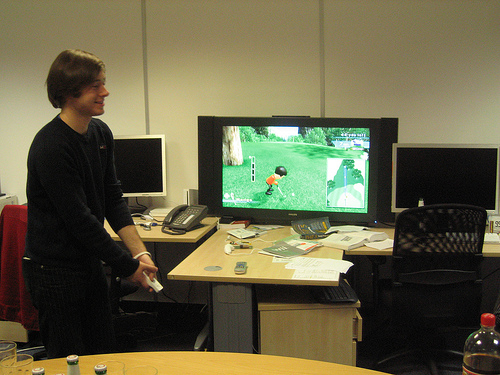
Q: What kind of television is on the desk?
A: An LED.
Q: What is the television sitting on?
A: A desk.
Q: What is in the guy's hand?
A: A wii remote.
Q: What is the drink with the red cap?
A: A soda.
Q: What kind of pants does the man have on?
A: Black jeans.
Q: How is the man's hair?
A: Long.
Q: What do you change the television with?
A: Remote.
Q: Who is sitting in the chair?
A: There isn't.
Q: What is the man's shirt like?
A: Black with long sleeves.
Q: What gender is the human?
A: A man.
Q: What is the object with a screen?
A: A tv.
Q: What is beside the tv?
A: A monitor.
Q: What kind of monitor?
A: Computer monitor.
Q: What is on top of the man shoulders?
A: A head.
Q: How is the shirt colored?
A: Black.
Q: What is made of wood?
A: Table.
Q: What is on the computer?
A: A golf game.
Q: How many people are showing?
A: One.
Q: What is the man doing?
A: Playing a game.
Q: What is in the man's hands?
A: A controller.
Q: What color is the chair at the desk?
A: Black.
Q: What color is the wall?
A: White.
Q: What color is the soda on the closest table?
A: Brown.